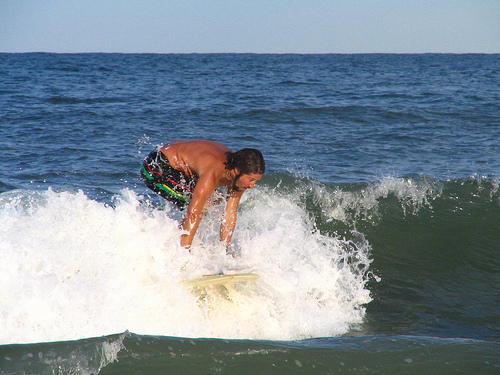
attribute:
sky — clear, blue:
[1, 2, 499, 55]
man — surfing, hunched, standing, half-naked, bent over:
[140, 138, 266, 277]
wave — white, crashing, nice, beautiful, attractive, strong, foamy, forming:
[3, 169, 499, 375]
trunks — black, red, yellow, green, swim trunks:
[141, 149, 196, 212]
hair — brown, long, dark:
[223, 146, 267, 177]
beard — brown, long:
[230, 173, 245, 192]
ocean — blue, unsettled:
[1, 50, 497, 374]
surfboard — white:
[177, 271, 261, 302]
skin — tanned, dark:
[160, 138, 263, 260]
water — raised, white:
[5, 184, 429, 344]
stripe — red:
[142, 157, 191, 192]